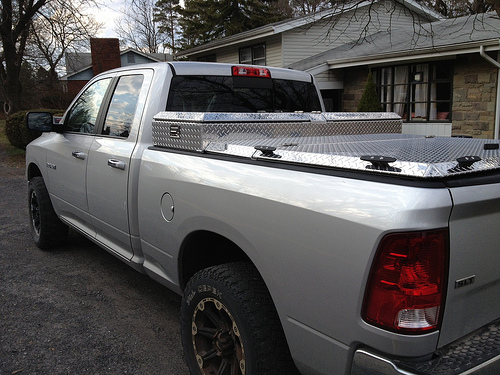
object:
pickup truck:
[24, 59, 499, 374]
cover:
[204, 130, 499, 178]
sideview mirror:
[25, 111, 56, 132]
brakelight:
[358, 223, 453, 337]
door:
[86, 68, 159, 260]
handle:
[105, 155, 126, 170]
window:
[100, 74, 143, 139]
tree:
[0, 0, 51, 115]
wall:
[337, 51, 499, 139]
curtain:
[377, 63, 438, 118]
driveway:
[1, 170, 180, 374]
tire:
[177, 258, 291, 373]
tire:
[26, 174, 69, 250]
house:
[170, 0, 500, 138]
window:
[375, 60, 453, 123]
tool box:
[151, 108, 405, 151]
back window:
[164, 76, 323, 114]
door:
[46, 76, 114, 240]